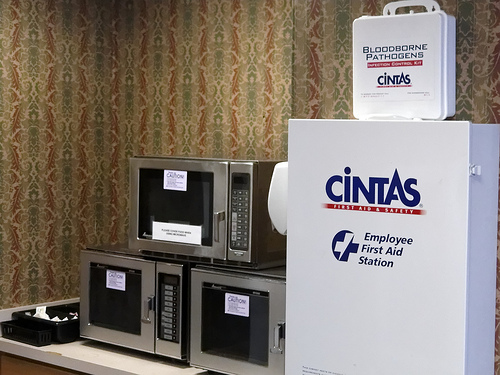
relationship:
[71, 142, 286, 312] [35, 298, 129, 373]
microwave on counter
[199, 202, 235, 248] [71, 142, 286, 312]
handle on microwave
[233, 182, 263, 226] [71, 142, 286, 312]
button on microwave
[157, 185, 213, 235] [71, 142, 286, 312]
door on microwave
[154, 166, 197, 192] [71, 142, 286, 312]
label on microwave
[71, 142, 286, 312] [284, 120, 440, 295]
microwave next to first aid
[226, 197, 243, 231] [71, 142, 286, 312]
number on microwave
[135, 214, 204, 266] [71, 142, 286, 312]
sticker on microwave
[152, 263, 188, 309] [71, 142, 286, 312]
food selector on microwave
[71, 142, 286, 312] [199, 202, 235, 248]
microwave has handle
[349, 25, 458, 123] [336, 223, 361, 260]
first aid has symbol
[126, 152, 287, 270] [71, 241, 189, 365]
microwave on top of microwave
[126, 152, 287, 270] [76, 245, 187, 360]
microwave on top of microwave